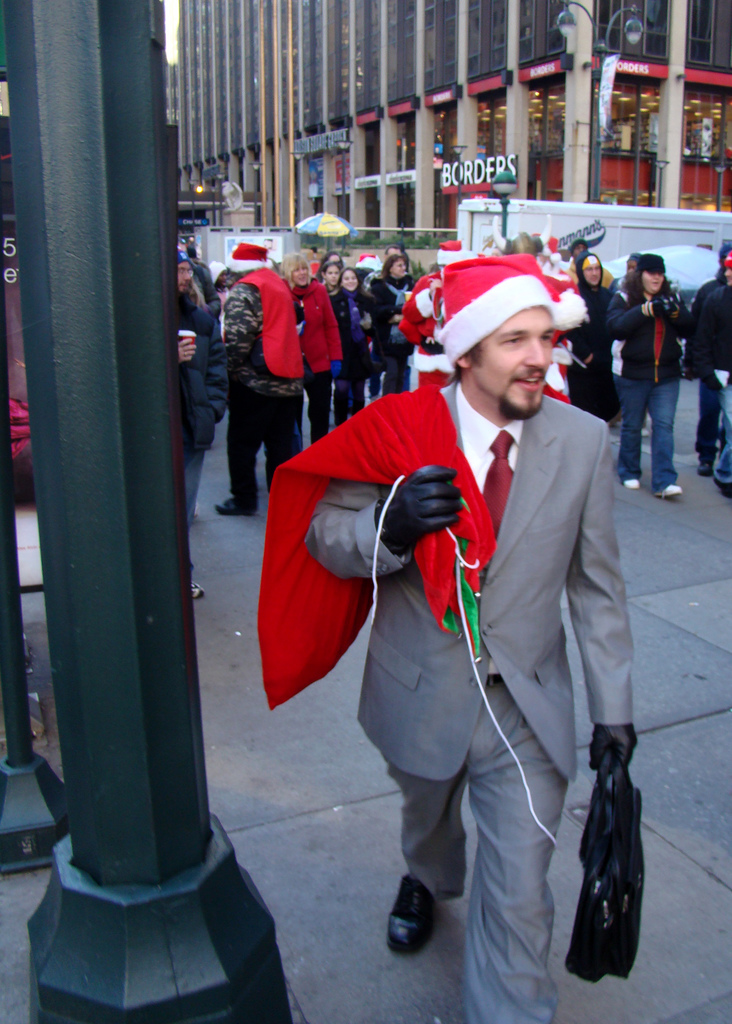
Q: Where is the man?
A: A city sidewalk.